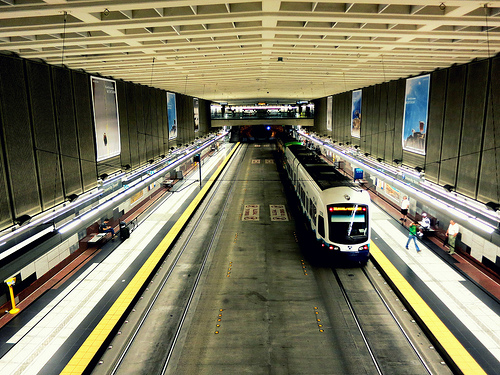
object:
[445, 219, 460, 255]
person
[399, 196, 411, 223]
person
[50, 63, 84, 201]
panel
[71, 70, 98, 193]
panel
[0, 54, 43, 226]
panel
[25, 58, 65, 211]
panel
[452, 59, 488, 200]
panel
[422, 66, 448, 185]
panel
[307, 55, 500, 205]
wall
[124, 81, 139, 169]
panel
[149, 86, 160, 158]
panel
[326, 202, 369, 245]
windshield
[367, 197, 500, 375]
sidewalk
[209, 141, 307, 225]
ground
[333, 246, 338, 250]
headlight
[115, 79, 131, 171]
panel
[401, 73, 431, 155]
poster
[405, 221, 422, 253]
person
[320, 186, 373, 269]
train engine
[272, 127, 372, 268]
train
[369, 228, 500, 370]
line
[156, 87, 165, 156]
panel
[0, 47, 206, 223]
wall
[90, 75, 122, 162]
poster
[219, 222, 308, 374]
ground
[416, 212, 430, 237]
person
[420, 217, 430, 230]
shirt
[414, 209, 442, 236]
bench